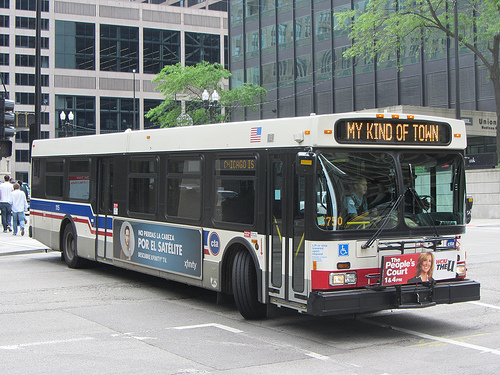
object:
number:
[319, 216, 343, 226]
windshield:
[312, 147, 465, 231]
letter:
[385, 124, 393, 141]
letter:
[395, 123, 403, 141]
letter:
[373, 123, 379, 140]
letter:
[356, 122, 363, 139]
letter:
[378, 123, 385, 141]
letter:
[431, 125, 439, 142]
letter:
[365, 123, 374, 140]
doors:
[262, 146, 308, 306]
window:
[310, 145, 464, 229]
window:
[162, 159, 202, 220]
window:
[125, 159, 156, 216]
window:
[63, 158, 92, 201]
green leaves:
[173, 70, 218, 90]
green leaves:
[349, 10, 421, 49]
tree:
[144, 60, 269, 129]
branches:
[481, 0, 500, 52]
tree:
[327, 0, 498, 102]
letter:
[347, 121, 356, 140]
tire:
[230, 246, 270, 320]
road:
[1, 204, 500, 374]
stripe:
[26, 197, 114, 238]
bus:
[30, 111, 482, 321]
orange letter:
[346, 122, 438, 142]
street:
[2, 215, 500, 374]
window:
[205, 158, 259, 218]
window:
[129, 155, 157, 217]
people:
[0, 174, 32, 237]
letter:
[412, 124, 418, 142]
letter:
[402, 123, 409, 141]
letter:
[419, 124, 426, 141]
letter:
[424, 124, 432, 141]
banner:
[381, 251, 459, 286]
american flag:
[249, 126, 262, 143]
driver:
[338, 177, 369, 230]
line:
[354, 314, 500, 357]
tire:
[60, 219, 83, 268]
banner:
[111, 216, 204, 281]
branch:
[397, 24, 440, 39]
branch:
[367, 9, 438, 35]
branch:
[425, 0, 442, 27]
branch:
[433, 0, 442, 11]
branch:
[360, 0, 404, 14]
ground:
[0, 216, 499, 375]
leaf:
[165, 65, 171, 70]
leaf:
[200, 60, 204, 64]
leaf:
[200, 77, 205, 81]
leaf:
[427, 55, 430, 61]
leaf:
[395, 65, 401, 71]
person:
[0, 175, 11, 233]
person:
[8, 182, 29, 236]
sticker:
[249, 126, 263, 143]